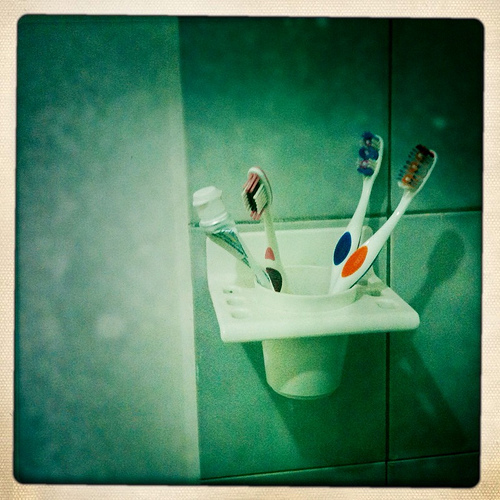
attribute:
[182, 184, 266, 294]
toothpaste — white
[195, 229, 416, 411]
holder — holed, white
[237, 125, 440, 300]
brushes — orange, blue, pink, bristled, white, colored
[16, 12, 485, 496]
wall — green